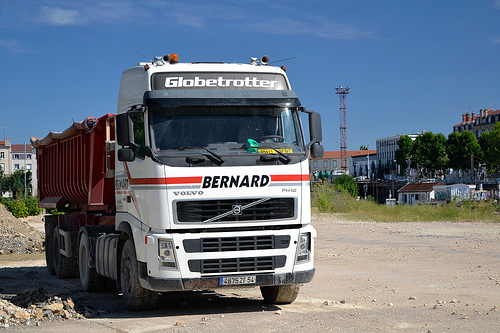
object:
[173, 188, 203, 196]
model name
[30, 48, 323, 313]
truck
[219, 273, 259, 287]
license plate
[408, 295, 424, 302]
rocks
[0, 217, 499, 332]
ground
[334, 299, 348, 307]
rocks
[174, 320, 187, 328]
rocks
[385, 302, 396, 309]
rocks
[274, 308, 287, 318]
rocks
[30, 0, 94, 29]
clouds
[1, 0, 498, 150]
sky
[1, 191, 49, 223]
bushes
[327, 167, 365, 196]
bushes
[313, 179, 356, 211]
bushes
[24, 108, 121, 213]
bin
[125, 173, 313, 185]
stripe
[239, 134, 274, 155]
hat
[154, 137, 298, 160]
dashboard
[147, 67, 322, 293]
front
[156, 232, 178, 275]
headlight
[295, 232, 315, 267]
headlight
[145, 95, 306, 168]
windshield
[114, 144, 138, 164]
mirror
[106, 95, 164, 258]
side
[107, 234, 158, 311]
wheel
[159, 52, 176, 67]
horn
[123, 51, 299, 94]
top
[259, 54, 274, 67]
horn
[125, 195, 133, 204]
tank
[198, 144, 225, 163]
windshield wiper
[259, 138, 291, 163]
windshield wiper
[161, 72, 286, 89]
globetrotter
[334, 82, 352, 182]
tower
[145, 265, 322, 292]
bumper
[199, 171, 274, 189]
bernard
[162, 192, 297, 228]
grill